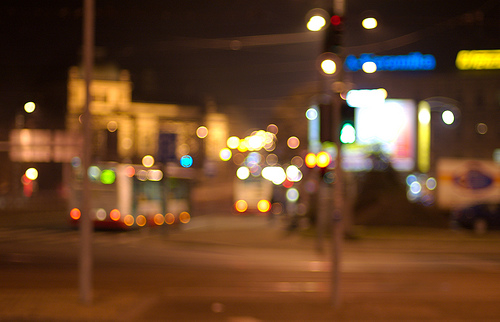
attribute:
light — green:
[340, 120, 355, 144]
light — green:
[87, 171, 124, 188]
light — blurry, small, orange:
[178, 211, 191, 223]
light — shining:
[22, 98, 37, 115]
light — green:
[97, 166, 119, 190]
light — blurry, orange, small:
[110, 207, 122, 220]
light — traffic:
[173, 127, 213, 155]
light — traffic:
[250, 123, 285, 149]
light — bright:
[302, 14, 327, 33]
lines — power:
[131, 25, 311, 75]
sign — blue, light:
[343, 42, 450, 85]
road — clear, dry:
[1, 215, 499, 319]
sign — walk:
[333, 100, 358, 145]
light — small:
[178, 207, 191, 226]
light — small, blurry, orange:
[308, 153, 334, 166]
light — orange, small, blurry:
[111, 209, 122, 224]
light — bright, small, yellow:
[317, 149, 329, 166]